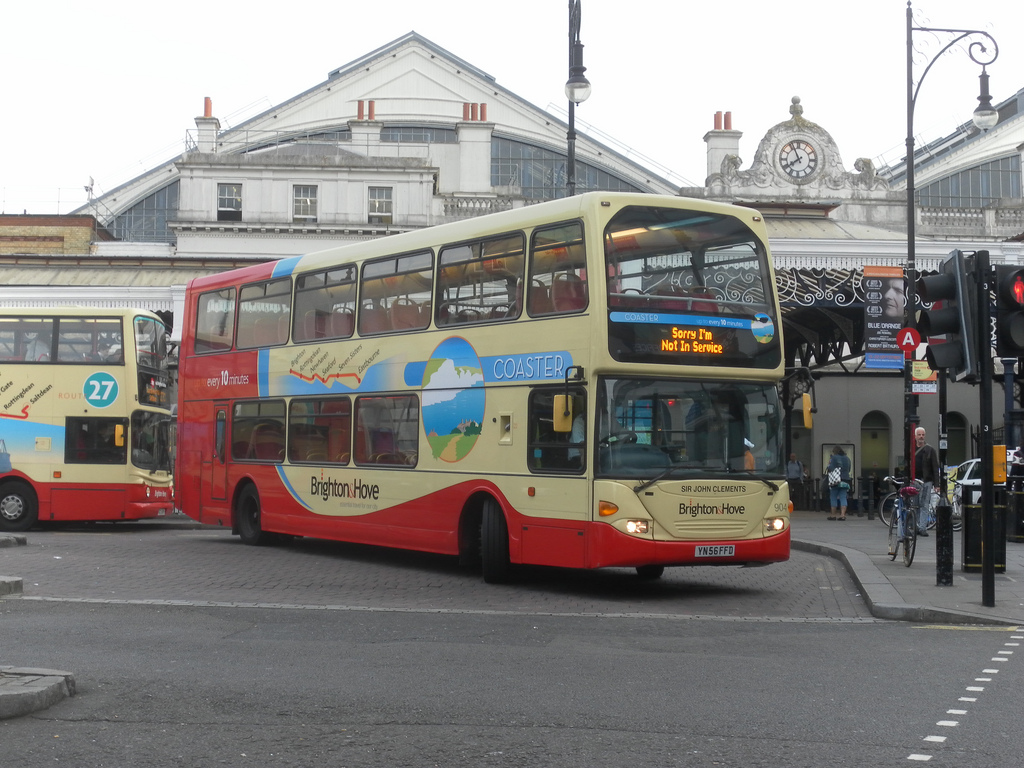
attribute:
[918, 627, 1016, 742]
lines — white, crosswalk, painted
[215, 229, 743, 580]
bus — double decker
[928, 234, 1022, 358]
light — red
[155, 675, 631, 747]
crack — long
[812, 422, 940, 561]
woman — standing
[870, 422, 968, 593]
guy — standing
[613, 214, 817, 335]
windshield — top deck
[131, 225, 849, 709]
bus — Yellow, red 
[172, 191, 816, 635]
bus — DOUBLE, DECK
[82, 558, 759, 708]
street — city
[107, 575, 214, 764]
roadway — gray, paved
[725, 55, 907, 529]
tower — decorative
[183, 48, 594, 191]
building — white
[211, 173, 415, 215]
windows — three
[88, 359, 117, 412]
number — 27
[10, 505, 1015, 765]
street — city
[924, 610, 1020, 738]
lines — white, painted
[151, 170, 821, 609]
bus — red, blue, cream, yellow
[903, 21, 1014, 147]
street light — decorative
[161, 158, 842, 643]
bus — yellow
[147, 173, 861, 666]
bus — yellow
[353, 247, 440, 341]
bus — yellow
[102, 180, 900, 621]
bus — yellow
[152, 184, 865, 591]
bus — yellow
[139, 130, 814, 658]
bus — red, yellow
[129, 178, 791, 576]
bus — RED, TAN, BLUE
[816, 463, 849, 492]
bag — WHITE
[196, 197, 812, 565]
bus — DOUBLE, DECK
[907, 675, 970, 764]
line — DOTTED, WHITE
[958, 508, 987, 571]
can — BLACK, TRASH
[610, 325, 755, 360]
sign — ORANGE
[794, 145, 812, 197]
clock — BLACK, WHITE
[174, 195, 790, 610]
bus — WHITE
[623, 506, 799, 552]
light — HEAD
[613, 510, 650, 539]
light — WHITE, HEAD